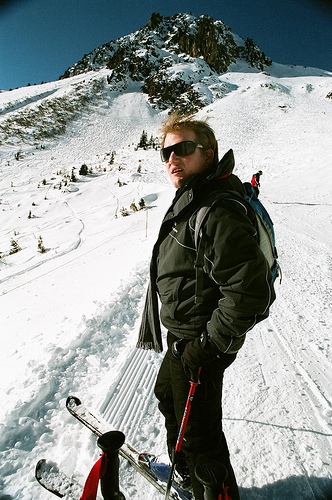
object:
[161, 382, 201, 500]
pole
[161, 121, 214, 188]
head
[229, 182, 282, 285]
backpack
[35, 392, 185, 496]
skis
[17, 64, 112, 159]
snow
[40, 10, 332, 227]
mountain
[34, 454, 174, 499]
skis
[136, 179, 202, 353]
scarf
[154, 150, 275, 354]
jacket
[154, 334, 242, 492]
pants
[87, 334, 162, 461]
ski tracks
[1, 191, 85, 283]
ski tracks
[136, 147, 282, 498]
ski gear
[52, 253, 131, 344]
snow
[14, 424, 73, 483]
snow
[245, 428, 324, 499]
snow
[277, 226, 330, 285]
snow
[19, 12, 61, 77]
sky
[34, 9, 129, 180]
skies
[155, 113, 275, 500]
man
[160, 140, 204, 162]
glasses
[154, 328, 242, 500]
pair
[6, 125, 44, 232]
snow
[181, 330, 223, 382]
gloves